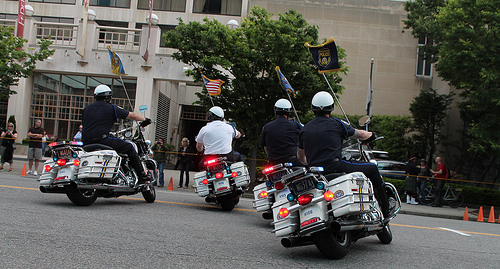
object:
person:
[404, 156, 420, 205]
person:
[0, 121, 19, 172]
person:
[26, 118, 46, 176]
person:
[175, 137, 194, 189]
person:
[428, 156, 447, 208]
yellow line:
[0, 184, 500, 236]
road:
[0, 176, 500, 269]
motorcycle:
[35, 104, 159, 207]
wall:
[247, 0, 463, 117]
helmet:
[273, 97, 293, 117]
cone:
[487, 206, 496, 223]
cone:
[476, 206, 484, 222]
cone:
[462, 206, 469, 221]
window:
[413, 28, 435, 80]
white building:
[0, 0, 242, 172]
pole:
[197, 65, 216, 107]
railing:
[33, 21, 80, 49]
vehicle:
[341, 148, 410, 180]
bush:
[160, 3, 353, 168]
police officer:
[296, 90, 392, 219]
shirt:
[296, 114, 358, 166]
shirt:
[193, 119, 240, 156]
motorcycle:
[192, 150, 253, 213]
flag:
[105, 44, 128, 75]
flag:
[201, 74, 227, 96]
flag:
[274, 65, 297, 99]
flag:
[303, 36, 342, 75]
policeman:
[80, 83, 157, 184]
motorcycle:
[259, 113, 404, 260]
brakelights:
[215, 172, 224, 179]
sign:
[15, 0, 27, 50]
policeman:
[194, 105, 244, 170]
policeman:
[259, 97, 310, 211]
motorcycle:
[251, 161, 310, 226]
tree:
[403, 86, 458, 171]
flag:
[16, 0, 26, 40]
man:
[193, 104, 247, 204]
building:
[0, 0, 500, 185]